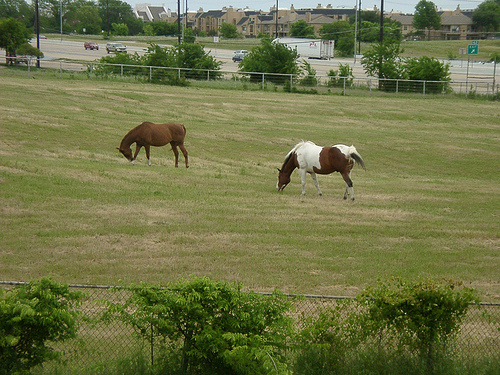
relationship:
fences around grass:
[1, 275, 500, 368] [2, 70, 496, 296]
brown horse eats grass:
[119, 118, 190, 171] [2, 70, 496, 296]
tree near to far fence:
[1, 2, 45, 66] [1, 47, 500, 95]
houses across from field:
[129, 2, 486, 35] [2, 70, 496, 296]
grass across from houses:
[2, 70, 496, 296] [129, 2, 486, 35]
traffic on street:
[78, 37, 340, 61] [1, 36, 497, 93]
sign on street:
[460, 40, 483, 67] [1, 36, 497, 93]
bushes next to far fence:
[90, 42, 447, 85] [1, 47, 500, 95]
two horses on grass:
[117, 115, 368, 201] [2, 70, 496, 296]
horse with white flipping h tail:
[272, 138, 370, 201] [347, 134, 373, 171]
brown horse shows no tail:
[119, 118, 190, 171] [347, 134, 373, 171]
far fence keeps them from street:
[1, 47, 500, 95] [1, 36, 497, 93]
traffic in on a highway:
[78, 37, 340, 61] [1, 36, 497, 93]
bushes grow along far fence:
[90, 42, 447, 85] [1, 47, 500, 95]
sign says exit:
[460, 40, 483, 67] [467, 42, 477, 58]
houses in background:
[129, 2, 486, 35] [5, 0, 497, 98]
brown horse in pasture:
[119, 118, 190, 171] [2, 70, 496, 296]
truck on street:
[262, 34, 334, 61] [1, 36, 497, 93]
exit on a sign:
[467, 42, 477, 58] [460, 40, 483, 67]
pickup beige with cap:
[103, 41, 132, 54] [107, 41, 117, 49]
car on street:
[81, 37, 103, 54] [1, 36, 497, 93]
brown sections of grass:
[1, 200, 219, 296] [2, 70, 496, 296]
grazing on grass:
[110, 144, 298, 192] [2, 70, 496, 296]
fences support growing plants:
[1, 275, 500, 368] [3, 279, 470, 372]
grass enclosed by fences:
[2, 70, 496, 296] [1, 275, 500, 368]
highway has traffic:
[1, 36, 497, 93] [78, 37, 340, 61]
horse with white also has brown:
[272, 138, 370, 201] [323, 147, 344, 173]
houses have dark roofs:
[129, 2, 486, 35] [139, 2, 370, 17]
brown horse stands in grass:
[119, 118, 190, 171] [2, 70, 496, 296]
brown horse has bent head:
[119, 118, 190, 171] [115, 134, 139, 169]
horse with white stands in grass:
[272, 138, 370, 201] [2, 70, 496, 296]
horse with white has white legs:
[272, 138, 370, 201] [294, 173, 329, 206]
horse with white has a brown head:
[272, 138, 370, 201] [275, 151, 296, 192]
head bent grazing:
[115, 134, 139, 169] [110, 144, 298, 192]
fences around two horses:
[1, 275, 500, 368] [117, 115, 368, 201]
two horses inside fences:
[117, 115, 368, 201] [1, 275, 500, 368]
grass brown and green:
[2, 70, 496, 296] [62, 344, 142, 374]